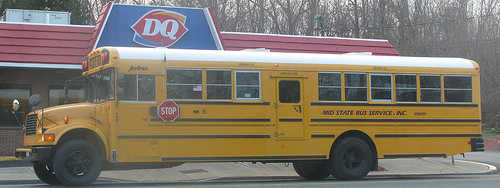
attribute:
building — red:
[1, 3, 402, 155]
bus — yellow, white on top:
[15, 47, 487, 186]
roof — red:
[1, 2, 399, 66]